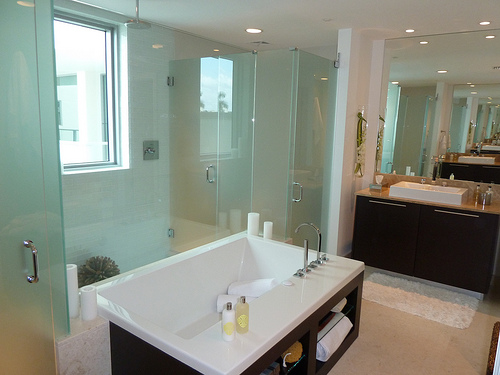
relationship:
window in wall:
[45, 26, 130, 154] [3, 21, 228, 221]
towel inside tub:
[36, 246, 100, 328] [314, 298, 367, 342]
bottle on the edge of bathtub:
[219, 302, 234, 341] [83, 233, 366, 373]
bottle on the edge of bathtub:
[238, 296, 246, 332] [83, 233, 366, 373]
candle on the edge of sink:
[373, 167, 388, 196] [389, 181, 469, 206]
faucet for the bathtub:
[413, 142, 448, 190] [83, 233, 366, 373]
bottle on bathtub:
[191, 287, 261, 359] [83, 233, 366, 373]